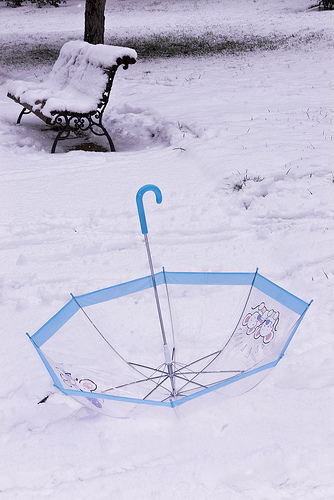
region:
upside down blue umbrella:
[17, 164, 315, 421]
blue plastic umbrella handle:
[130, 181, 162, 240]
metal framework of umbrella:
[120, 346, 245, 398]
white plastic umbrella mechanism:
[161, 341, 174, 375]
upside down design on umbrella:
[242, 298, 281, 349]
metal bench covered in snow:
[5, 28, 140, 152]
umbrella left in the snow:
[17, 169, 319, 443]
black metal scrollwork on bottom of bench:
[47, 113, 112, 155]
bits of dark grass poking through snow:
[170, 101, 332, 216]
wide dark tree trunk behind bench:
[76, 3, 138, 150]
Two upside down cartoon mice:
[230, 300, 279, 358]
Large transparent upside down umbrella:
[26, 183, 313, 419]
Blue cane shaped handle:
[135, 182, 163, 233]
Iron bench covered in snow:
[6, 38, 136, 155]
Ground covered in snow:
[0, 0, 333, 498]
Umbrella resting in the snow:
[26, 182, 314, 419]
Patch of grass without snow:
[2, 23, 313, 68]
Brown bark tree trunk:
[82, 0, 107, 47]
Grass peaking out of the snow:
[225, 165, 267, 207]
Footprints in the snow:
[1, 205, 331, 258]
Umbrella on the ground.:
[52, 205, 294, 418]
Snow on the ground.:
[65, 412, 296, 476]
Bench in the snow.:
[29, 30, 126, 146]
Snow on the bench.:
[36, 47, 116, 147]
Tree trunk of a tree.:
[76, 3, 115, 53]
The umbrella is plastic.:
[59, 289, 232, 414]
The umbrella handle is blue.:
[129, 177, 171, 230]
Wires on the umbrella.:
[130, 357, 223, 394]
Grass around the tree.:
[160, 28, 261, 54]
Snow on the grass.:
[150, 34, 255, 63]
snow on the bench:
[37, 72, 97, 109]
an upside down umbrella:
[30, 194, 303, 413]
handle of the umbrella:
[125, 185, 175, 230]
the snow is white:
[56, 429, 260, 496]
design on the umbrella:
[242, 312, 285, 344]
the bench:
[25, 98, 125, 135]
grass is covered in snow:
[226, 172, 276, 193]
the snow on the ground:
[188, 75, 273, 126]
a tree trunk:
[78, 0, 110, 38]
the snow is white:
[26, 170, 103, 247]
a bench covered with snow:
[5, 38, 138, 154]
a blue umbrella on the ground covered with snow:
[26, 183, 314, 422]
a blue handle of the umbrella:
[134, 183, 162, 235]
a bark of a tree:
[82, 0, 104, 43]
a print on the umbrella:
[242, 301, 279, 343]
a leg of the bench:
[50, 129, 69, 152]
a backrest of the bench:
[55, 39, 137, 101]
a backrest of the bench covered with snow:
[54, 39, 137, 101]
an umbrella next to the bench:
[0, 36, 315, 423]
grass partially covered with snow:
[172, 36, 264, 52]